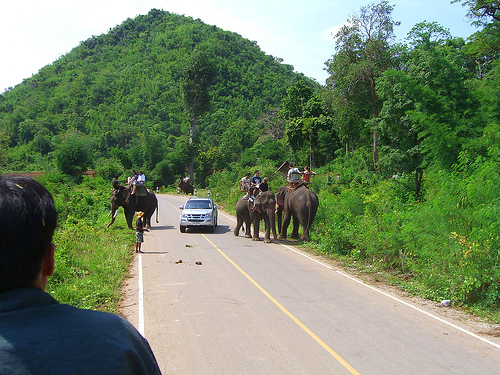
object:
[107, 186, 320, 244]
animals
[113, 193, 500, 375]
road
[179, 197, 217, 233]
truck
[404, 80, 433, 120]
green leaves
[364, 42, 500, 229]
tree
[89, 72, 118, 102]
leaves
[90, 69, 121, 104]
tree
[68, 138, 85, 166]
leaves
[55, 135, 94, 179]
tree